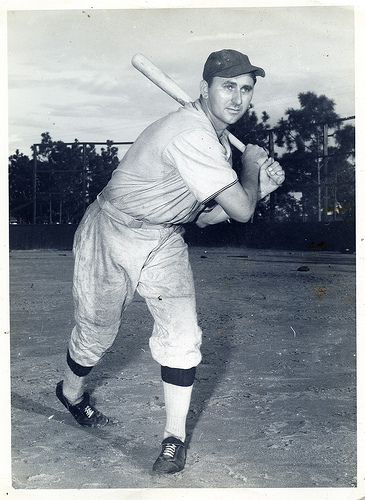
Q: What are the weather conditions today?
A: It is cloudy.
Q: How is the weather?
A: It is cloudy.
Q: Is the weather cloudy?
A: Yes, it is cloudy.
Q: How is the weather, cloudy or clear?
A: It is cloudy.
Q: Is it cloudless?
A: No, it is cloudy.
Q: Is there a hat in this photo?
A: Yes, there is a hat.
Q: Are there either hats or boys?
A: Yes, there is a hat.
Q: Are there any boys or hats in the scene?
A: Yes, there is a hat.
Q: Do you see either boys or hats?
A: Yes, there is a hat.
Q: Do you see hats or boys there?
A: Yes, there is a hat.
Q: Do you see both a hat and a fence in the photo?
A: Yes, there are both a hat and a fence.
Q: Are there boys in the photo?
A: No, there are no boys.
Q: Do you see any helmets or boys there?
A: No, there are no boys or helmets.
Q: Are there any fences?
A: Yes, there is a fence.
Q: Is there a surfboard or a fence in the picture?
A: Yes, there is a fence.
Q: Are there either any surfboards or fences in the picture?
A: Yes, there is a fence.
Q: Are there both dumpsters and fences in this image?
A: No, there is a fence but no dumpsters.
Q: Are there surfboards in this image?
A: No, there are no surfboards.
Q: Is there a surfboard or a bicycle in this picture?
A: No, there are no surfboards or bicycles.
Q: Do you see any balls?
A: No, there are no balls.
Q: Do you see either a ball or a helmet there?
A: No, there are no balls or helmets.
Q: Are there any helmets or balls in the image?
A: No, there are no balls or helmets.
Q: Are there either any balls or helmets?
A: No, there are no balls or helmets.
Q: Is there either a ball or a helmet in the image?
A: No, there are no balls or helmets.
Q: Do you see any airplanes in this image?
A: No, there are no airplanes.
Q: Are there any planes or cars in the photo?
A: No, there are no planes or cars.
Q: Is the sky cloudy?
A: Yes, the sky is cloudy.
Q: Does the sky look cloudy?
A: Yes, the sky is cloudy.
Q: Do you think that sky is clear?
A: No, the sky is cloudy.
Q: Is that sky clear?
A: No, the sky is cloudy.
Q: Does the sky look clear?
A: No, the sky is cloudy.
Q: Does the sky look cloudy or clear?
A: The sky is cloudy.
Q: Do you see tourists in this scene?
A: No, there are no tourists.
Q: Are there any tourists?
A: No, there are no tourists.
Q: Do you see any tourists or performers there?
A: No, there are no tourists or performers.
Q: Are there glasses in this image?
A: No, there are no glasses.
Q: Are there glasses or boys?
A: No, there are no glasses or boys.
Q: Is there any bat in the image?
A: Yes, there is a bat.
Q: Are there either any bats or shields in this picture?
A: Yes, there is a bat.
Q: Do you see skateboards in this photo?
A: No, there are no skateboards.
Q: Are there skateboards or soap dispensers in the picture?
A: No, there are no skateboards or soap dispensers.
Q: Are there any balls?
A: No, there are no balls.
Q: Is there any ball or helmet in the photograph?
A: No, there are no balls or helmets.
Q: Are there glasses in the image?
A: No, there are no glasses.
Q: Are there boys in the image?
A: No, there are no boys.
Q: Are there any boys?
A: No, there are no boys.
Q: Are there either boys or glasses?
A: No, there are no boys or glasses.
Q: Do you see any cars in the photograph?
A: No, there are no cars.